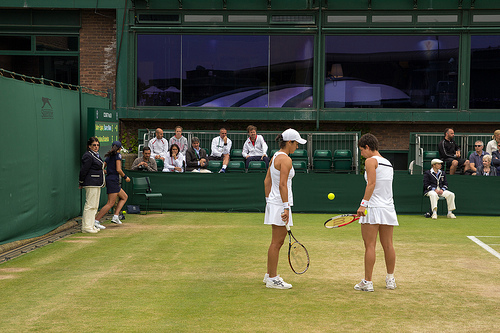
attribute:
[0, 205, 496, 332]
tennis court — grass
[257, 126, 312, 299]
woman — baseball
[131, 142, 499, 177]
seating — plastic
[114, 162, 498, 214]
screen — green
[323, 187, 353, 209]
ball — tennis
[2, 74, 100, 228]
wall — green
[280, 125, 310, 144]
cap — white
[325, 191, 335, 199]
ball — tennis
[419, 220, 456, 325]
grass — green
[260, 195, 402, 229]
dresses — sport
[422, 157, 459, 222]
official — tennis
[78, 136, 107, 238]
official — tennis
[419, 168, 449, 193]
blazer — blue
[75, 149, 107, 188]
blazer — blue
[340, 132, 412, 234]
uniform — white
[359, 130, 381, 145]
hair — short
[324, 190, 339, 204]
ball — tennis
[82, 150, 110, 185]
jacket — dark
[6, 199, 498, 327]
court — tennis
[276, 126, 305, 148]
cap — white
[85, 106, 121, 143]
scoreboard — green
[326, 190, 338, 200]
ball — green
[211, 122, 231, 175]
spectator — seated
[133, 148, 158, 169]
spectator — seated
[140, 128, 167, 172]
spectator — seated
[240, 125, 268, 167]
spectator — seated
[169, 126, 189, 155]
spectator — seated